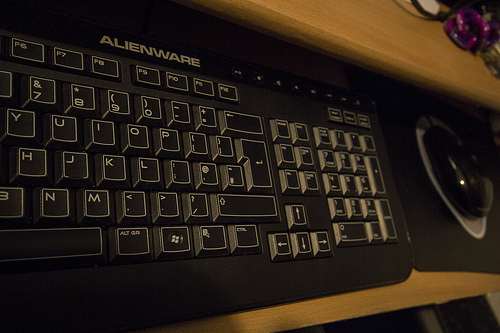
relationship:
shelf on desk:
[194, 0, 499, 109] [182, 0, 499, 331]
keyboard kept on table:
[0, 1, 413, 332] [126, 3, 498, 332]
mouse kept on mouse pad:
[426, 119, 486, 217] [368, 103, 498, 277]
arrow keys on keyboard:
[262, 199, 336, 264] [0, 1, 413, 332]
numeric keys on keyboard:
[312, 121, 402, 255] [0, 1, 413, 332]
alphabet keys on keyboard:
[6, 103, 180, 226] [0, 1, 413, 332]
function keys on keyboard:
[8, 30, 242, 108] [0, 1, 413, 332]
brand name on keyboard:
[92, 32, 202, 68] [0, 1, 413, 332]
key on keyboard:
[155, 223, 191, 259] [0, 1, 413, 332]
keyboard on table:
[0, 1, 413, 332] [126, 3, 498, 332]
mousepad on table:
[370, 102, 499, 273] [126, 3, 498, 332]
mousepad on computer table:
[370, 95, 499, 278] [133, 0, 499, 332]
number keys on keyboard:
[315, 121, 396, 239] [14, 24, 406, 313]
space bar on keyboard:
[3, 226, 105, 259] [14, 24, 406, 313]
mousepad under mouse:
[370, 102, 499, 273] [423, 124, 482, 229]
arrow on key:
[317, 238, 323, 241] [311, 227, 326, 257]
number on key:
[142, 106, 151, 114] [142, 90, 168, 122]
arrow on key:
[278, 241, 292, 246] [264, 230, 290, 260]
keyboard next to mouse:
[14, 24, 406, 313] [424, 121, 481, 221]